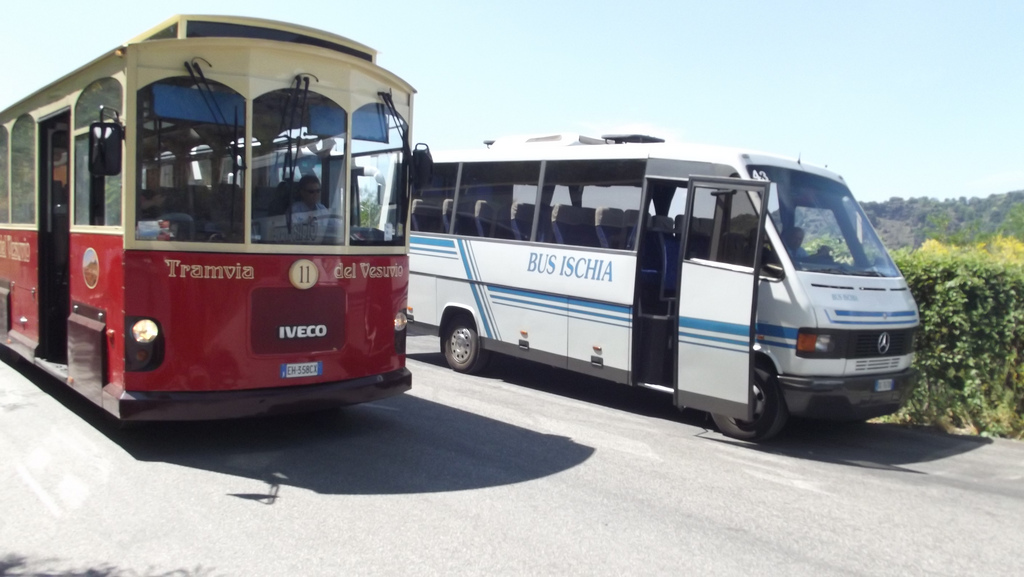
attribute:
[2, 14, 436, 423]
bus — red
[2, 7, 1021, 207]
sky — blue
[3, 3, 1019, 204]
clouds — white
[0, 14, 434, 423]
tram — tan, white, red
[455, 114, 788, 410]
bus — white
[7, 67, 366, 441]
trolley — red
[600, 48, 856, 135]
sky — blue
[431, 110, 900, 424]
bus — white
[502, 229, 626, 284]
writing — blue